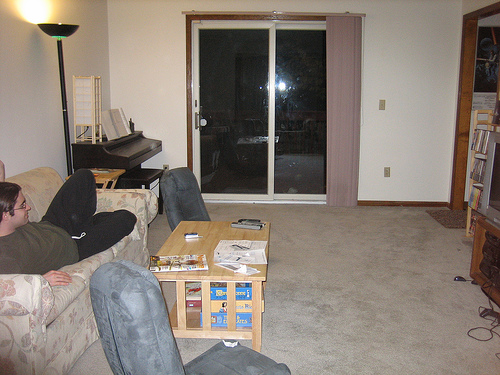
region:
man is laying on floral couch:
[0, 165, 158, 374]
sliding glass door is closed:
[187, 17, 336, 204]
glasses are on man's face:
[1, 199, 26, 215]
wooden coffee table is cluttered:
[142, 219, 271, 351]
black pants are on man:
[42, 167, 137, 260]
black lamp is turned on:
[35, 21, 100, 176]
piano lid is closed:
[97, 129, 164, 166]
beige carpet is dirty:
[62, 199, 498, 374]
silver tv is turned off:
[474, 129, 499, 226]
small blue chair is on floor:
[90, 260, 292, 374]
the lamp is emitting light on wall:
[16, 1, 93, 189]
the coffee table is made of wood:
[159, 214, 266, 345]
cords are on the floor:
[438, 262, 497, 369]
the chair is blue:
[93, 263, 277, 368]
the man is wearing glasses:
[0, 181, 42, 227]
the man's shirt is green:
[0, 225, 90, 275]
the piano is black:
[71, 104, 206, 218]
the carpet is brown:
[277, 211, 473, 368]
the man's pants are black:
[41, 177, 146, 261]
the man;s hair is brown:
[0, 173, 24, 221]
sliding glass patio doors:
[184, 11, 331, 204]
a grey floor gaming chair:
[84, 256, 283, 373]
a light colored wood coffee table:
[150, 212, 268, 349]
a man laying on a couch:
[0, 154, 157, 366]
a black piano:
[72, 119, 166, 205]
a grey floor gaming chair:
[157, 165, 220, 233]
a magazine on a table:
[143, 249, 217, 281]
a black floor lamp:
[29, 11, 89, 182]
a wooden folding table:
[61, 159, 122, 191]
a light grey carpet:
[276, 202, 443, 364]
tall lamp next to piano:
[30, 17, 92, 175]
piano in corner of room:
[57, 91, 189, 221]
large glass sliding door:
[167, 11, 372, 213]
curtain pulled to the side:
[317, 11, 370, 228]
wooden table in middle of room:
[159, 203, 261, 333]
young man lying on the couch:
[4, 163, 159, 270]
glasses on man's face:
[10, 202, 30, 214]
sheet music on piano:
[94, 99, 141, 143]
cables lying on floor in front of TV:
[438, 264, 498, 356]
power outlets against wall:
[382, 160, 394, 183]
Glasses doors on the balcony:
[191, 18, 325, 200]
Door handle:
[193, 110, 203, 130]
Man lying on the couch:
[0, 165, 140, 285]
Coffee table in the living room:
[145, 218, 270, 352]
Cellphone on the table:
[183, 230, 203, 238]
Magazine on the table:
[147, 252, 209, 271]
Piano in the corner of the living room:
[71, 130, 163, 169]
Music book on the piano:
[99, 106, 132, 140]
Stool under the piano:
[121, 166, 164, 214]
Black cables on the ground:
[451, 271, 498, 342]